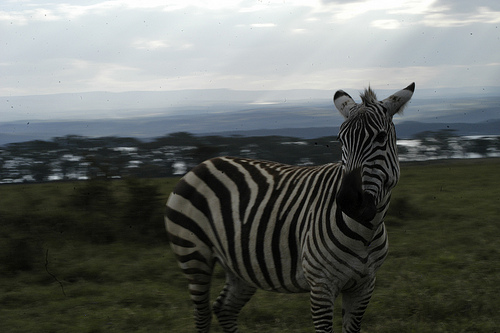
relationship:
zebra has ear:
[160, 80, 423, 333] [333, 89, 359, 119]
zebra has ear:
[160, 80, 423, 333] [380, 79, 419, 118]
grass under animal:
[1, 154, 499, 328] [120, 67, 443, 329]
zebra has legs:
[195, 79, 456, 271] [184, 268, 379, 331]